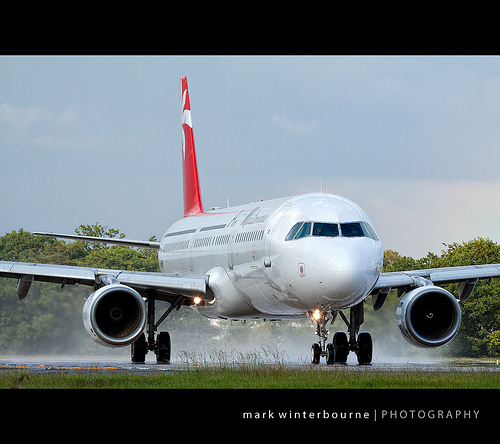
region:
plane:
[14, 59, 489, 380]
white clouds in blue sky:
[230, 95, 307, 150]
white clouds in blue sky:
[367, 86, 405, 124]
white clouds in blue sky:
[300, 132, 375, 182]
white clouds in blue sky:
[394, 45, 462, 119]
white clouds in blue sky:
[400, 173, 495, 224]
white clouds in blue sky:
[318, 75, 380, 126]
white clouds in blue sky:
[227, 109, 278, 153]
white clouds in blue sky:
[68, 101, 136, 166]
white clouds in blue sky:
[38, 133, 112, 178]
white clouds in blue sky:
[439, 150, 497, 210]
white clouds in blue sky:
[369, 125, 401, 156]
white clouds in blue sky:
[383, 123, 428, 168]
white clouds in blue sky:
[309, 110, 391, 155]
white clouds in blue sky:
[229, 90, 289, 128]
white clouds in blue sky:
[29, 77, 69, 114]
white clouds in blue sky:
[34, 183, 88, 218]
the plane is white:
[102, 183, 382, 373]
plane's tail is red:
[160, 75, 212, 230]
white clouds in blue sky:
[412, 111, 456, 164]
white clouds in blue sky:
[398, 141, 430, 192]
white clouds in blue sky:
[251, 116, 296, 143]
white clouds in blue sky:
[284, 80, 321, 120]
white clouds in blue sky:
[214, 83, 265, 134]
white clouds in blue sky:
[62, 77, 84, 103]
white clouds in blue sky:
[74, 150, 109, 180]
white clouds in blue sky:
[127, 173, 167, 222]